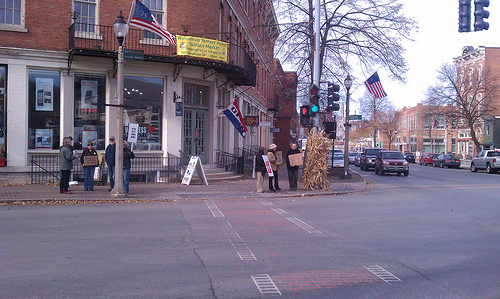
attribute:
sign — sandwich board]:
[180, 154, 211, 189]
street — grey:
[3, 174, 499, 298]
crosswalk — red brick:
[220, 197, 384, 298]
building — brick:
[1, 1, 280, 180]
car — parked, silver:
[472, 149, 499, 174]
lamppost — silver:
[346, 74, 352, 176]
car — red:
[374, 148, 407, 177]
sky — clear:
[271, 2, 499, 113]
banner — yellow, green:
[175, 33, 231, 64]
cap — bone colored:
[270, 141, 280, 153]